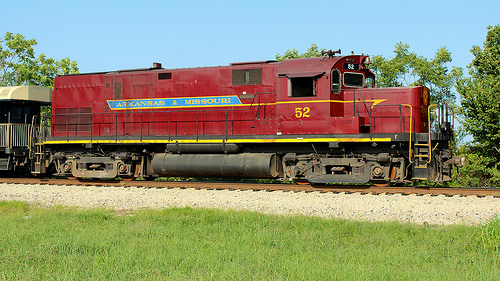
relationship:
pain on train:
[88, 105, 259, 127] [43, 49, 469, 186]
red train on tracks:
[43, 49, 469, 186] [434, 185, 499, 197]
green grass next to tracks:
[0, 209, 499, 279] [434, 185, 499, 197]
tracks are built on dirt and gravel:
[422, 183, 499, 196] [288, 196, 499, 217]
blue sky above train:
[1, 0, 486, 33] [43, 49, 469, 186]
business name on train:
[107, 94, 242, 108] [43, 49, 469, 186]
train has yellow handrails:
[43, 49, 469, 186] [399, 101, 438, 166]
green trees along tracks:
[466, 25, 500, 191] [434, 185, 499, 197]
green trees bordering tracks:
[466, 25, 500, 191] [434, 185, 499, 197]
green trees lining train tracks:
[466, 25, 500, 191] [407, 183, 499, 196]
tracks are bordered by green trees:
[422, 183, 499, 196] [466, 25, 500, 191]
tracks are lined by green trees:
[422, 183, 499, 196] [466, 25, 500, 191]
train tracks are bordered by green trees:
[407, 183, 499, 196] [466, 25, 500, 191]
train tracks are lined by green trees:
[407, 183, 499, 196] [466, 25, 500, 191]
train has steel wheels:
[43, 49, 469, 186] [371, 161, 397, 189]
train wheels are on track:
[371, 161, 397, 189] [417, 183, 499, 198]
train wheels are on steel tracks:
[371, 161, 397, 189] [407, 183, 499, 196]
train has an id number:
[43, 49, 469, 186] [293, 105, 311, 121]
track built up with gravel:
[395, 183, 500, 198] [309, 193, 499, 222]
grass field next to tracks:
[1, 221, 496, 280] [381, 184, 499, 198]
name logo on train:
[107, 94, 242, 108] [43, 49, 469, 186]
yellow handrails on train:
[399, 101, 438, 166] [43, 49, 469, 186]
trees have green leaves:
[457, 23, 500, 189] [466, 25, 500, 191]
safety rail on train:
[50, 106, 278, 141] [43, 49, 469, 186]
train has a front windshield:
[43, 49, 469, 186] [345, 72, 364, 88]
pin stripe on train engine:
[243, 99, 387, 109] [43, 49, 469, 186]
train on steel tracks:
[43, 49, 469, 186] [395, 183, 500, 198]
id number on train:
[293, 105, 311, 121] [43, 49, 469, 186]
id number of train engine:
[293, 105, 311, 121] [43, 49, 469, 186]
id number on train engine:
[293, 105, 311, 121] [43, 49, 469, 186]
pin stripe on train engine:
[43, 136, 394, 146] [43, 49, 469, 186]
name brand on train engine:
[107, 94, 242, 108] [43, 49, 469, 186]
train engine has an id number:
[43, 49, 469, 186] [293, 105, 311, 121]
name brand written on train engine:
[107, 94, 242, 108] [43, 49, 469, 186]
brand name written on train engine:
[107, 94, 242, 108] [43, 49, 469, 186]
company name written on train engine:
[107, 94, 242, 108] [43, 49, 469, 186]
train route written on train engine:
[107, 94, 242, 108] [43, 49, 469, 186]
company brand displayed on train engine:
[107, 94, 242, 108] [43, 49, 469, 186]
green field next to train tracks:
[1, 221, 496, 280] [407, 183, 499, 196]